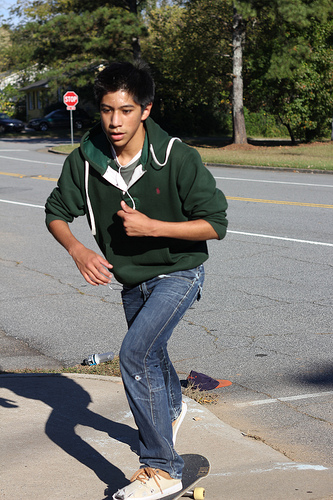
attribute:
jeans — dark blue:
[114, 259, 216, 468]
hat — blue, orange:
[169, 346, 233, 412]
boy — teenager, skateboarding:
[47, 66, 228, 498]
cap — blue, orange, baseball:
[185, 369, 234, 390]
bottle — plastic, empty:
[79, 353, 114, 368]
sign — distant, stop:
[63, 89, 79, 138]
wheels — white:
[193, 485, 204, 497]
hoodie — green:
[45, 116, 227, 285]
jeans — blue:
[117, 263, 204, 479]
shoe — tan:
[111, 464, 184, 499]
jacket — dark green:
[44, 116, 229, 285]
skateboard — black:
[158, 453, 209, 499]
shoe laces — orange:
[129, 465, 170, 493]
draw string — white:
[82, 160, 95, 235]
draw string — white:
[148, 136, 184, 167]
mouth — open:
[105, 129, 126, 142]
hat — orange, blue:
[186, 368, 236, 390]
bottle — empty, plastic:
[83, 349, 115, 368]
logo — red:
[152, 185, 162, 196]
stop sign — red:
[62, 89, 80, 112]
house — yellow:
[21, 77, 56, 117]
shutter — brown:
[32, 94, 39, 112]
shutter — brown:
[25, 96, 30, 109]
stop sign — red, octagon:
[60, 87, 81, 112]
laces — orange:
[128, 466, 158, 479]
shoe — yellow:
[113, 472, 185, 497]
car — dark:
[25, 104, 90, 134]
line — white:
[249, 386, 329, 408]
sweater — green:
[41, 118, 228, 290]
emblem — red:
[153, 184, 162, 195]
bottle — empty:
[79, 348, 116, 373]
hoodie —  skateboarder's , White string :
[66, 133, 194, 241]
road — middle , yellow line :
[241, 239, 288, 287]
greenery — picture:
[178, 42, 291, 138]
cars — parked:
[1, 105, 66, 137]